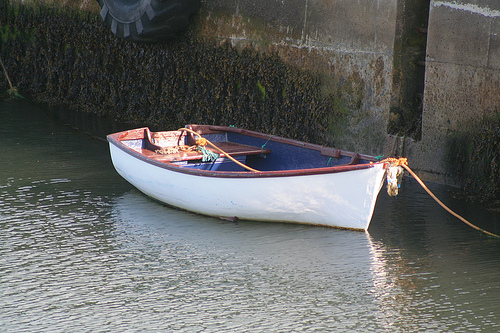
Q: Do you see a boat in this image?
A: Yes, there is a boat.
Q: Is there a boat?
A: Yes, there is a boat.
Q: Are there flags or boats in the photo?
A: Yes, there is a boat.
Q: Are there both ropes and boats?
A: Yes, there are both a boat and a rope.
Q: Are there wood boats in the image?
A: Yes, there is a wood boat.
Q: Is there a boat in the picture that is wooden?
A: Yes, there is a boat that is wooden.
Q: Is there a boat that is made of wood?
A: Yes, there is a boat that is made of wood.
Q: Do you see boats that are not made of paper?
A: Yes, there is a boat that is made of wood.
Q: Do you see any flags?
A: No, there are no flags.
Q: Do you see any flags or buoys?
A: No, there are no flags or buoys.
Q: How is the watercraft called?
A: The watercraft is a boat.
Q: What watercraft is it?
A: The watercraft is a boat.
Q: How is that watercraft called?
A: This is a boat.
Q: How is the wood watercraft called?
A: The watercraft is a boat.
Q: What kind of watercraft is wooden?
A: The watercraft is a boat.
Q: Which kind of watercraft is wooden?
A: The watercraft is a boat.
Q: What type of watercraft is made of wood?
A: The watercraft is a boat.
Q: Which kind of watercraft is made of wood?
A: The watercraft is a boat.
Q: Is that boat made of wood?
A: Yes, the boat is made of wood.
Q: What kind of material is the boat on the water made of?
A: The boat is made of wood.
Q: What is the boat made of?
A: The boat is made of wood.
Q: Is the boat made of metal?
A: No, the boat is made of wood.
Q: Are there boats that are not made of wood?
A: No, there is a boat but it is made of wood.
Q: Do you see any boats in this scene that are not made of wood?
A: No, there is a boat but it is made of wood.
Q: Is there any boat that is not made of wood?
A: No, there is a boat but it is made of wood.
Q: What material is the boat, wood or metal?
A: The boat is made of wood.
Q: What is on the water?
A: The boat is on the water.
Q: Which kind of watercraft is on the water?
A: The watercraft is a boat.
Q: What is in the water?
A: The boat is in the water.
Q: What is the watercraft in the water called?
A: The watercraft is a boat.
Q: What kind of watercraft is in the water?
A: The watercraft is a boat.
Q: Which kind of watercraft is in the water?
A: The watercraft is a boat.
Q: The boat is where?
A: The boat is in the water.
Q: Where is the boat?
A: The boat is in the water.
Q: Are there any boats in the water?
A: Yes, there is a boat in the water.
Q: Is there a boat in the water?
A: Yes, there is a boat in the water.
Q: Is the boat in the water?
A: Yes, the boat is in the water.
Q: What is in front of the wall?
A: The boat is in front of the wall.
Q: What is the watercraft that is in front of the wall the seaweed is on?
A: The watercraft is a boat.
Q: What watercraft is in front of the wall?
A: The watercraft is a boat.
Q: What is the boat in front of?
A: The boat is in front of the wall.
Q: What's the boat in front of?
A: The boat is in front of the wall.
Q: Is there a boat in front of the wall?
A: Yes, there is a boat in front of the wall.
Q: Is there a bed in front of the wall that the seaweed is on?
A: No, there is a boat in front of the wall.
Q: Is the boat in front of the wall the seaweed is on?
A: Yes, the boat is in front of the wall.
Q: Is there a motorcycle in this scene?
A: No, there are no motorcycles.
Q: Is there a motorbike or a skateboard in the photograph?
A: No, there are no motorcycles or skateboards.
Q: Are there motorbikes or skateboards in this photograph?
A: No, there are no motorbikes or skateboards.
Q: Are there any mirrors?
A: No, there are no mirrors.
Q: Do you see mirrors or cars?
A: No, there are no mirrors or cars.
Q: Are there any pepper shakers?
A: No, there are no pepper shakers.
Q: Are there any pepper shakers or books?
A: No, there are no pepper shakers or books.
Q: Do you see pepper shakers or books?
A: No, there are no pepper shakers or books.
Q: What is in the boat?
A: The rope is in the boat.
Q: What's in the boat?
A: The rope is in the boat.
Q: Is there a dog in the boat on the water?
A: No, there is a rope in the boat.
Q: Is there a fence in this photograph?
A: No, there are no fences.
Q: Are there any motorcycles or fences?
A: No, there are no fences or motorcycles.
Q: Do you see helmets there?
A: No, there are no helmets.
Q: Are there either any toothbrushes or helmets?
A: No, there are no helmets or toothbrushes.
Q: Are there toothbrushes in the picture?
A: No, there are no toothbrushes.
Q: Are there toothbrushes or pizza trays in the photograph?
A: No, there are no toothbrushes or pizza trays.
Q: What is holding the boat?
A: The rope is holding the boat.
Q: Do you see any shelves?
A: No, there are no shelves.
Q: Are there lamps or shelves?
A: No, there are no shelves or lamps.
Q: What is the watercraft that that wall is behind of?
A: The watercraft is a boat.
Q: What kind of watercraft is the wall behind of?
A: The wall is behind the boat.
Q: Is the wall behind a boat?
A: Yes, the wall is behind a boat.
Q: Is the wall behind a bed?
A: No, the wall is behind a boat.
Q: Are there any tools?
A: No, there are no tools.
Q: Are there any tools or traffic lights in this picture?
A: No, there are no tools or traffic lights.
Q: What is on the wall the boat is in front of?
A: The seaweed is on the wall.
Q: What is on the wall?
A: The seaweed is on the wall.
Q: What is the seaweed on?
A: The seaweed is on the wall.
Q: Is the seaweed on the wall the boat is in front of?
A: Yes, the seaweed is on the wall.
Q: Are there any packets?
A: No, there are no packets.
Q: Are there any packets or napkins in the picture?
A: No, there are no packets or napkins.